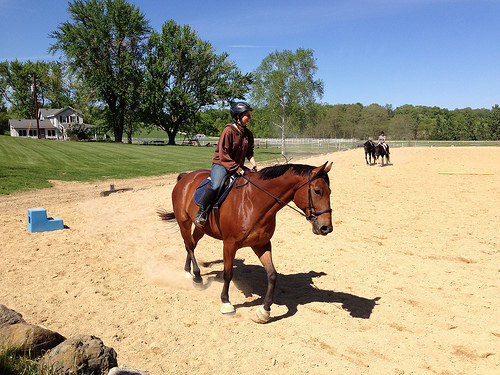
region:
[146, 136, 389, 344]
the horse is brown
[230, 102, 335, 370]
the horse is brown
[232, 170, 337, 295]
the horse is brown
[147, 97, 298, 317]
the horse is brown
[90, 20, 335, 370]
the horse is brown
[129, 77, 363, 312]
horse with rider on its back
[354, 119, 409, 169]
two horses walking on dirt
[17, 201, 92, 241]
blue step on dirt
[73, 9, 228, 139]
green leaves on trees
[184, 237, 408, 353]
shadow of horse and rider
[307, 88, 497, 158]
group of trees in the distance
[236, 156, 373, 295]
brown horse with black mane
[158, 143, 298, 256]
blue blanket on horse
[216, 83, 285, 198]
brown jacket on rider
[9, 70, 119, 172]
green lawn in front of house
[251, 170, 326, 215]
brown horse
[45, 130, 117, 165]
The green grass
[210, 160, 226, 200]
Women is wearing blue jeans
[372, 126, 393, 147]
Person riding a horse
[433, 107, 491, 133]
Green bushes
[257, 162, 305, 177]
Black hair on the horse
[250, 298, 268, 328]
Shoe of the horse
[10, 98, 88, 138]
house in the background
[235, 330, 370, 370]
The horse is standing on sand.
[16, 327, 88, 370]
Rocks on the side of sand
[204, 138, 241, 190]
the horse is brown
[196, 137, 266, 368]
the horse is brown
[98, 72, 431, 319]
young person riding horse in rural area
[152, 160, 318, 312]
horse is brown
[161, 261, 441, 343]
arena has a sandy surface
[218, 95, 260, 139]
person wearing helmet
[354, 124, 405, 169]
rider with extra horse in arena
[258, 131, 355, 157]
white fence in the distance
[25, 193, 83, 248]
blue steps to get on the horse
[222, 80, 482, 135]
trees in the background on flat land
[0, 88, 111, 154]
farmhouse in the background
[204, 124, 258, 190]
person riding wearing brown sweatshirt